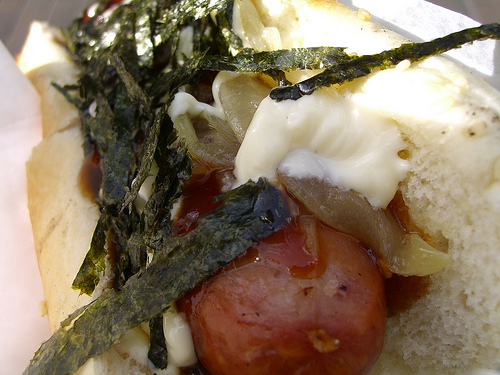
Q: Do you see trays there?
A: No, there are no trays.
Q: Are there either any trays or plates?
A: No, there are no trays or plates.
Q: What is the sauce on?
A: The sauce is on the hot dog.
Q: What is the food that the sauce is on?
A: The food is a hot dog.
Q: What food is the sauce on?
A: The sauce is on the hot dog.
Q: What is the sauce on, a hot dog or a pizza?
A: The sauce is on a hot dog.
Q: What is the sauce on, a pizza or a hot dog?
A: The sauce is on a hot dog.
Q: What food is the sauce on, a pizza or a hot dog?
A: The sauce is on a hot dog.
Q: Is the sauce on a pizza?
A: No, the sauce is on a hot dog.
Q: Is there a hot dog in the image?
A: Yes, there is a hot dog.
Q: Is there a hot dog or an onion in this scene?
A: Yes, there is a hot dog.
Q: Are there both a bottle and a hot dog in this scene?
A: No, there is a hot dog but no bottles.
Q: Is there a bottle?
A: No, there are no bottles.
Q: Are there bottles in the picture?
A: No, there are no bottles.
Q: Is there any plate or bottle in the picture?
A: No, there are no bottles or plates.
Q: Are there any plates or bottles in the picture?
A: No, there are no bottles or plates.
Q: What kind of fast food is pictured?
A: The fast food is a hot dog.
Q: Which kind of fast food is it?
A: The food is a hot dog.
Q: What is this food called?
A: That is a hot dog.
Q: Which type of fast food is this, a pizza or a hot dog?
A: That is a hot dog.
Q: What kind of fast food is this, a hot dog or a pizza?
A: That is a hot dog.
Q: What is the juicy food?
A: The food is a hot dog.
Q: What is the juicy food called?
A: The food is a hot dog.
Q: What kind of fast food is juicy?
A: The fast food is a hot dog.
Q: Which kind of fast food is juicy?
A: The fast food is a hot dog.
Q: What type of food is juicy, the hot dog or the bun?
A: The hot dog is juicy.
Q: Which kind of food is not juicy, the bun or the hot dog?
A: The bun is not juicy.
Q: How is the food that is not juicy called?
A: The food is a bun.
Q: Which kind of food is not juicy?
A: The food is a bun.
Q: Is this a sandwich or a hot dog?
A: This is a hot dog.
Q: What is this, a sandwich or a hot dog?
A: This is a hot dog.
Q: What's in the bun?
A: The hot dog is in the bun.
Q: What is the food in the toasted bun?
A: The food is a hot dog.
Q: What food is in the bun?
A: The food is a hot dog.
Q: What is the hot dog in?
A: The hot dog is in the bun.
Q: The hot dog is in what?
A: The hot dog is in the bun.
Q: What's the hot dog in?
A: The hot dog is in the bun.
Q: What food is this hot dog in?
A: The hot dog is in the bun.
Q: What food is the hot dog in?
A: The hot dog is in the bun.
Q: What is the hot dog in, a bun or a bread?
A: The hot dog is in a bun.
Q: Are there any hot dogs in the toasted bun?
A: Yes, there is a hot dog in the bun.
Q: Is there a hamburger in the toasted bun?
A: No, there is a hot dog in the bun.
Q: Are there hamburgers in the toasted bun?
A: No, there is a hot dog in the bun.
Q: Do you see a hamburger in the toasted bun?
A: No, there is a hot dog in the bun.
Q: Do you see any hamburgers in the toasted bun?
A: No, there is a hot dog in the bun.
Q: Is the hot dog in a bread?
A: No, the hot dog is in the bun.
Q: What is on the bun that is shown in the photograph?
A: The hot dog is on the bun.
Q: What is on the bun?
A: The hot dog is on the bun.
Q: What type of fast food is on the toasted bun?
A: The food is a hot dog.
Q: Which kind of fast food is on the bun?
A: The food is a hot dog.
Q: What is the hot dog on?
A: The hot dog is on the bun.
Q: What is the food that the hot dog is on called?
A: The food is a bun.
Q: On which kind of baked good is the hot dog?
A: The hot dog is on the bun.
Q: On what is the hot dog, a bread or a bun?
A: The hot dog is on a bun.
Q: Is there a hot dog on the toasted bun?
A: Yes, there is a hot dog on the bun.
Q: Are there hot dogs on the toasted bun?
A: Yes, there is a hot dog on the bun.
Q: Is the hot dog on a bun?
A: Yes, the hot dog is on a bun.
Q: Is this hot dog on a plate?
A: No, the hot dog is on a bun.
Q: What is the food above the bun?
A: The food is a hot dog.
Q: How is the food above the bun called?
A: The food is a hot dog.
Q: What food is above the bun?
A: The food is a hot dog.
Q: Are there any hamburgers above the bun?
A: No, there is a hot dog above the bun.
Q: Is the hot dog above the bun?
A: Yes, the hot dog is above the bun.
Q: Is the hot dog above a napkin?
A: No, the hot dog is above the bun.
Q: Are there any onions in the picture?
A: Yes, there are onions.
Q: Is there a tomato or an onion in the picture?
A: Yes, there are onions.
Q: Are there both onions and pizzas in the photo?
A: No, there are onions but no pizzas.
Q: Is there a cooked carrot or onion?
A: Yes, there are cooked onions.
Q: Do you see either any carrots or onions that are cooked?
A: Yes, the onions are cooked.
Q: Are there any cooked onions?
A: Yes, there are cooked onions.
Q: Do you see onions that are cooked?
A: Yes, there are onions that are cooked.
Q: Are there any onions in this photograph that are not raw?
A: Yes, there are cooked onions.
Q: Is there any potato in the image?
A: No, there are no potatoes.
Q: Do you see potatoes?
A: No, there are no potatoes.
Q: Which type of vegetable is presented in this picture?
A: The vegetable is onions.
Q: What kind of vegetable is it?
A: The vegetables are onions.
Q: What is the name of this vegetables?
A: These are onions.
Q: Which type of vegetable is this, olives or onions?
A: These are onions.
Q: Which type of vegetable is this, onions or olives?
A: These are onions.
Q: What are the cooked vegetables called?
A: The vegetables are onions.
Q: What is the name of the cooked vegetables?
A: The vegetables are onions.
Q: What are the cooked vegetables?
A: The vegetables are onions.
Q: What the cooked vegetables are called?
A: The vegetables are onions.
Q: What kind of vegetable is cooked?
A: The vegetable is onions.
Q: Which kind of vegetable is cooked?
A: The vegetable is onions.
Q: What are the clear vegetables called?
A: The vegetables are onions.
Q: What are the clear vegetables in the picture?
A: The vegetables are onions.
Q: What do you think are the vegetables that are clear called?
A: The vegetables are onions.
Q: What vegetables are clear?
A: The vegetables are onions.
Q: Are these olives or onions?
A: These are onions.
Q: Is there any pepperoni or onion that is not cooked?
A: No, there are onions but they are cooked.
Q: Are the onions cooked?
A: Yes, the onions are cooked.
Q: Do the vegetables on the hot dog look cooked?
A: Yes, the onions are cooked.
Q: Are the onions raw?
A: No, the onions are cooked.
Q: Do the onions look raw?
A: No, the onions are cooked.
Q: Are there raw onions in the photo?
A: No, there are onions but they are cooked.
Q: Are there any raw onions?
A: No, there are onions but they are cooked.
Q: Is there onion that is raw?
A: No, there are onions but they are cooked.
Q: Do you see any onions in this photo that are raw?
A: No, there are onions but they are cooked.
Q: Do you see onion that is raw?
A: No, there are onions but they are cooked.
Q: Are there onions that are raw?
A: No, there are onions but they are cooked.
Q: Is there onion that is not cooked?
A: No, there are onions but they are cooked.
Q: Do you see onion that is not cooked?
A: No, there are onions but they are cooked.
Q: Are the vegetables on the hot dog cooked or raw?
A: The onions are cooked.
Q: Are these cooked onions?
A: Yes, these are cooked onions.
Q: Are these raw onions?
A: No, these are cooked onions.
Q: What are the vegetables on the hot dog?
A: The vegetables are onions.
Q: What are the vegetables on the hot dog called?
A: The vegetables are onions.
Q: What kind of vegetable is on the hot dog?
A: The vegetables are onions.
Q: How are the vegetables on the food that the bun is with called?
A: The vegetables are onions.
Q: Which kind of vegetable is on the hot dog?
A: The vegetables are onions.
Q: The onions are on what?
A: The onions are on the hot dog.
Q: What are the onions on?
A: The onions are on the hot dog.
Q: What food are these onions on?
A: The onions are on the hot dog.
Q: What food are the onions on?
A: The onions are on the hot dog.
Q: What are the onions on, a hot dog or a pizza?
A: The onions are on a hot dog.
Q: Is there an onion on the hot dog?
A: Yes, there are onions on the hot dog.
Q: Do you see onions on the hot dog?
A: Yes, there are onions on the hot dog.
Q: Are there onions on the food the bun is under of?
A: Yes, there are onions on the hot dog.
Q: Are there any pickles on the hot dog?
A: No, there are onions on the hot dog.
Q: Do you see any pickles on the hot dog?
A: No, there are onions on the hot dog.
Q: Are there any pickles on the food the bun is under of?
A: No, there are onions on the hot dog.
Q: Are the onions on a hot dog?
A: Yes, the onions are on a hot dog.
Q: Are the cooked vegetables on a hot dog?
A: Yes, the onions are on a hot dog.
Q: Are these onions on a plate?
A: No, the onions are on a hot dog.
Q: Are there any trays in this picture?
A: No, there are no trays.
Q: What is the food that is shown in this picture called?
A: The food is a bun.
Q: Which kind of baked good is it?
A: The food is a bun.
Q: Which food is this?
A: That is a bun.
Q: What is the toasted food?
A: The food is a bun.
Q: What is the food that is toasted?
A: The food is a bun.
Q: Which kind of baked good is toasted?
A: The baked good is a bun.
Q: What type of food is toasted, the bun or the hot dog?
A: The bun is toasted.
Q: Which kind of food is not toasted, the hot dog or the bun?
A: The hot dog is not toasted.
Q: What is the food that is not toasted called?
A: The food is a hot dog.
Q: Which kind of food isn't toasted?
A: The food is a hot dog.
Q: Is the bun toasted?
A: Yes, the bun is toasted.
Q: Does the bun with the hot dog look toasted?
A: Yes, the bun is toasted.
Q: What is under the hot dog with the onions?
A: The bun is under the hot dog.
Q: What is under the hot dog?
A: The bun is under the hot dog.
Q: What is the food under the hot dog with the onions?
A: The food is a bun.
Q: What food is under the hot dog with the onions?
A: The food is a bun.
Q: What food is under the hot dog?
A: The food is a bun.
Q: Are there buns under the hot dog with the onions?
A: Yes, there is a bun under the hot dog.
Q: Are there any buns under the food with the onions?
A: Yes, there is a bun under the hot dog.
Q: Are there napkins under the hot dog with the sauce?
A: No, there is a bun under the hot dog.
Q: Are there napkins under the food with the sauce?
A: No, there is a bun under the hot dog.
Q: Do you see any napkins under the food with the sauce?
A: No, there is a bun under the hot dog.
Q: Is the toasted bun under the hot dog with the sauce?
A: Yes, the bun is under the hot dog.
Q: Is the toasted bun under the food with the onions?
A: Yes, the bun is under the hot dog.